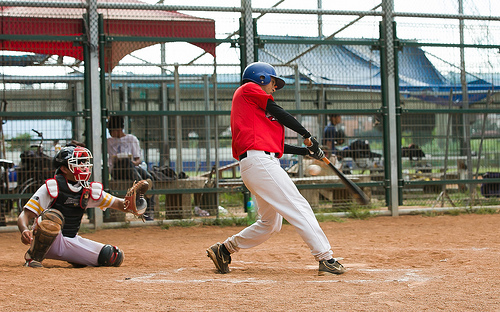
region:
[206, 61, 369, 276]
a baseball player swinging his bat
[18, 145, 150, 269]
a catcher crouching to receive a ball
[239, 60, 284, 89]
a blue hard hat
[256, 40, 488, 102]
a blue canopy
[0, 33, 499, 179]
a green metal fence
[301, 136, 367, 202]
man holding a black baseball bat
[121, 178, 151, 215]
a brown catcher's mitt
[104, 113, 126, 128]
person wearing a black hat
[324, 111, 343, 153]
man walking behind a fence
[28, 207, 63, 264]
catcher wearing knee protection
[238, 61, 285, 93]
a boy with a blue helmet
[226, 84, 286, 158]
a boy with a red shirt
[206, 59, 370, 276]
a boy swinging a bat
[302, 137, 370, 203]
a black and orange bat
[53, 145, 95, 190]
a black and red catchers mask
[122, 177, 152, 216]
a boy with a glove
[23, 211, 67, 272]
a boy with knee pads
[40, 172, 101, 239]
a catcher with a chest guard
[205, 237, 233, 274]
a boy with a grey shoe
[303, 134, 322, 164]
a boy with black gloves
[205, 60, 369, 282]
A baseball player swinging a bat.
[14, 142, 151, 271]
A catcher in a baseball game.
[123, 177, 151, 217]
A catcher's mitt.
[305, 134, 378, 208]
A black baseball bat.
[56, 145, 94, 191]
A baseball catcher's mask.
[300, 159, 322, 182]
A thrown baseball.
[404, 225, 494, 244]
The dirt on the field.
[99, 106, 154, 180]
A player in the dugout.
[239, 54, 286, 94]
A blue baseball helmet.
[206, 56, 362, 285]
A baseball player in a red jersey.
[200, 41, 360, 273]
this is a person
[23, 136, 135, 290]
this is a person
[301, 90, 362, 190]
this is a person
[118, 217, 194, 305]
this is dirt on the field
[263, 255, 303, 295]
this is dirt on the field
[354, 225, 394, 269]
this is dirt on the field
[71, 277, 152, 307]
this is dirt on the field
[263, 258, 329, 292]
this is dirt on the field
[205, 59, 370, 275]
A baseball player at bat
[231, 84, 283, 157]
A red baseball jersey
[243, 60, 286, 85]
A blue baseball helmet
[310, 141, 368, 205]
A black baseball bat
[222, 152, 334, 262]
A pair of white baseball pants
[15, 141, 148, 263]
A catcher on a baseball team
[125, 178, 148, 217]
A catcher's mitt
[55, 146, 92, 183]
A catcher's face mask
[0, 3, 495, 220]
A chain link fence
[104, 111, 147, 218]
A fan at a baseball game